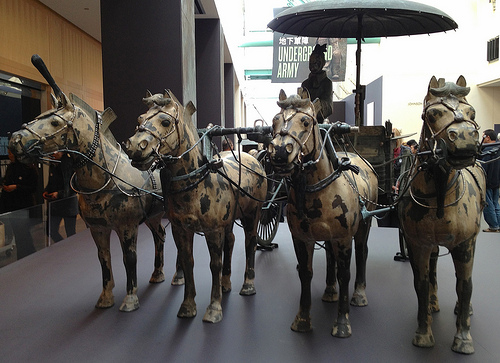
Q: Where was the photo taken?
A: It was taken at the museum.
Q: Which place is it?
A: It is a museum.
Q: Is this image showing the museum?
A: Yes, it is showing the museum.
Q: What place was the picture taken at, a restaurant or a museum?
A: It was taken at a museum.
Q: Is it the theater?
A: No, it is the museum.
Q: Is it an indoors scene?
A: Yes, it is indoors.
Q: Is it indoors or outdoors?
A: It is indoors.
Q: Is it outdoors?
A: No, it is indoors.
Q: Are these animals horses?
A: Yes, all the animals are horses.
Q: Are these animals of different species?
A: No, all the animals are horses.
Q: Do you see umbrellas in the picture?
A: Yes, there is an umbrella.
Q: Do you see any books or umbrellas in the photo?
A: Yes, there is an umbrella.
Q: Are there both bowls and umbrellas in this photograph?
A: No, there is an umbrella but no bowls.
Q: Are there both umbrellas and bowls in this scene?
A: No, there is an umbrella but no bowls.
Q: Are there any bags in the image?
A: No, there are no bags.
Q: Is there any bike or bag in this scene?
A: No, there are no bags or bikes.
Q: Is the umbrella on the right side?
A: Yes, the umbrella is on the right of the image.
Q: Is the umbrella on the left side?
A: No, the umbrella is on the right of the image.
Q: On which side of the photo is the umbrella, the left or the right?
A: The umbrella is on the right of the image.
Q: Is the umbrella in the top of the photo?
A: Yes, the umbrella is in the top of the image.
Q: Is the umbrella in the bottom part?
A: No, the umbrella is in the top of the image.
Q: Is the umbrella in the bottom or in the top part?
A: The umbrella is in the top of the image.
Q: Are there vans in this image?
A: No, there are no vans.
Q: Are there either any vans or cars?
A: No, there are no vans or cars.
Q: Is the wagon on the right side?
A: Yes, the wagon is on the right of the image.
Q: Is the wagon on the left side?
A: No, the wagon is on the right of the image.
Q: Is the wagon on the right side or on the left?
A: The wagon is on the right of the image.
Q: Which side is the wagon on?
A: The wagon is on the right of the image.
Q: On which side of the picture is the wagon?
A: The wagon is on the right of the image.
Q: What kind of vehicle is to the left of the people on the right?
A: The vehicle is a wagon.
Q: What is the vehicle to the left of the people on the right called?
A: The vehicle is a wagon.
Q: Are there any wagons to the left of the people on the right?
A: Yes, there is a wagon to the left of the people.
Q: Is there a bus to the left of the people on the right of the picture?
A: No, there is a wagon to the left of the people.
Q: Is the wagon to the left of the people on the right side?
A: Yes, the wagon is to the left of the people.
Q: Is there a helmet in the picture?
A: No, there are no helmets.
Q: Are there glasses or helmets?
A: No, there are no helmets or glasses.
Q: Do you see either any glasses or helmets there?
A: No, there are no helmets or glasses.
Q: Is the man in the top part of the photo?
A: Yes, the man is in the top of the image.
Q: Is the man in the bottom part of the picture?
A: No, the man is in the top of the image.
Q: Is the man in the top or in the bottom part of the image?
A: The man is in the top of the image.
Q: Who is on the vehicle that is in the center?
A: The man is on the carriage.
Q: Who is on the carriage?
A: The man is on the carriage.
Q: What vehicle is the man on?
A: The man is on the carriage.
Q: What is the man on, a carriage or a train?
A: The man is on a carriage.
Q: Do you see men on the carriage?
A: Yes, there is a man on the carriage.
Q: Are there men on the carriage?
A: Yes, there is a man on the carriage.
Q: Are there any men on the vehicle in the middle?
A: Yes, there is a man on the carriage.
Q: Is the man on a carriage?
A: Yes, the man is on a carriage.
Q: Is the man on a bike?
A: No, the man is on a carriage.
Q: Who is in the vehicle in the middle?
A: The man is in the carriage.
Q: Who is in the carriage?
A: The man is in the carriage.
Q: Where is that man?
A: The man is in the carriage.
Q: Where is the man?
A: The man is in the carriage.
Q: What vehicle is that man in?
A: The man is in the carriage.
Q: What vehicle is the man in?
A: The man is in the carriage.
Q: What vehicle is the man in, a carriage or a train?
A: The man is in a carriage.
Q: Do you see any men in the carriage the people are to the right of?
A: Yes, there is a man in the carriage.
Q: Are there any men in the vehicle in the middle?
A: Yes, there is a man in the carriage.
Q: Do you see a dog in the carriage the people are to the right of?
A: No, there is a man in the carriage.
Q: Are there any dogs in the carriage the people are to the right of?
A: No, there is a man in the carriage.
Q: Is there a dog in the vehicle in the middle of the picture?
A: No, there is a man in the carriage.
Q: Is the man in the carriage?
A: Yes, the man is in the carriage.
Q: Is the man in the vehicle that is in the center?
A: Yes, the man is in the carriage.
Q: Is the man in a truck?
A: No, the man is in the carriage.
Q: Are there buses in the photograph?
A: No, there are no buses.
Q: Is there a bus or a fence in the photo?
A: No, there are no buses or fences.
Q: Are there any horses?
A: Yes, there are horses.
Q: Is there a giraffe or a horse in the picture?
A: Yes, there are horses.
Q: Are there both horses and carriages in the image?
A: Yes, there are both horses and a carriage.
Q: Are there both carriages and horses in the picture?
A: Yes, there are both horses and a carriage.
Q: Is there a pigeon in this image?
A: No, there are no pigeons.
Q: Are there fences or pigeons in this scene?
A: No, there are no pigeons or fences.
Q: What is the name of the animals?
A: The animals are horses.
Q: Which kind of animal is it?
A: The animals are horses.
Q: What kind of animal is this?
A: These are horses.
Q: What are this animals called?
A: These are horses.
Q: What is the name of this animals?
A: These are horses.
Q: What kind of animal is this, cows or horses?
A: These are horses.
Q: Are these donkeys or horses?
A: These are horses.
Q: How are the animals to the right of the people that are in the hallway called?
A: The animals are horses.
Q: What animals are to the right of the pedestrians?
A: The animals are horses.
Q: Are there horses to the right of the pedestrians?
A: Yes, there are horses to the right of the pedestrians.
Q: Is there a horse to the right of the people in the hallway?
A: Yes, there are horses to the right of the pedestrians.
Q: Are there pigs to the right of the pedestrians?
A: No, there are horses to the right of the pedestrians.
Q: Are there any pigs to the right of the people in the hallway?
A: No, there are horses to the right of the pedestrians.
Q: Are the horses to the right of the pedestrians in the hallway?
A: Yes, the horses are to the right of the pedestrians.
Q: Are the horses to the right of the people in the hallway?
A: Yes, the horses are to the right of the pedestrians.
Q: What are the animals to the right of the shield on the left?
A: The animals are horses.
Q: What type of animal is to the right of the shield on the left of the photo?
A: The animals are horses.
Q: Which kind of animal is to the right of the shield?
A: The animals are horses.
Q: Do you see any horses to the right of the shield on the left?
A: Yes, there are horses to the right of the shield.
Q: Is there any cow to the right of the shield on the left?
A: No, there are horses to the right of the shield.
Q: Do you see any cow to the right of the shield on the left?
A: No, there are horses to the right of the shield.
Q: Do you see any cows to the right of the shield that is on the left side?
A: No, there are horses to the right of the shield.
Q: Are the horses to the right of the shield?
A: Yes, the horses are to the right of the shield.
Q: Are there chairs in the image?
A: No, there are no chairs.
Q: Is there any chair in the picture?
A: No, there are no chairs.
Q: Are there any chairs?
A: No, there are no chairs.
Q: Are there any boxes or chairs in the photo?
A: No, there are no chairs or boxes.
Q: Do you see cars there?
A: No, there are no cars.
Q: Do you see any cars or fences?
A: No, there are no cars or fences.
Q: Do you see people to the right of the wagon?
A: Yes, there are people to the right of the wagon.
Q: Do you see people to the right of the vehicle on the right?
A: Yes, there are people to the right of the wagon.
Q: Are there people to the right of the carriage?
A: Yes, there are people to the right of the carriage.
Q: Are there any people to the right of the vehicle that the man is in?
A: Yes, there are people to the right of the carriage.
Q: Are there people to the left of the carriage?
A: No, the people are to the right of the carriage.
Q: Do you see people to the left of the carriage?
A: No, the people are to the right of the carriage.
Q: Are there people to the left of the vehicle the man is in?
A: No, the people are to the right of the carriage.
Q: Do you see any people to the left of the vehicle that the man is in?
A: No, the people are to the right of the carriage.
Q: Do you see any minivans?
A: No, there are no minivans.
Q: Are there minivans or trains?
A: No, there are no minivans or trains.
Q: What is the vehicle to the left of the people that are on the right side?
A: The vehicle is a carriage.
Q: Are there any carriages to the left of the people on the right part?
A: Yes, there is a carriage to the left of the people.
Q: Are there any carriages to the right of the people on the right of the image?
A: No, the carriage is to the left of the people.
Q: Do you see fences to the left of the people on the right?
A: No, there is a carriage to the left of the people.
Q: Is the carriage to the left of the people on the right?
A: Yes, the carriage is to the left of the people.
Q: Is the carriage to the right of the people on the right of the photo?
A: No, the carriage is to the left of the people.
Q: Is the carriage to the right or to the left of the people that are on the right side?
A: The carriage is to the left of the people.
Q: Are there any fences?
A: No, there are no fences.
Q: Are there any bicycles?
A: No, there are no bicycles.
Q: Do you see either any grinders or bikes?
A: No, there are no bikes or grinders.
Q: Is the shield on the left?
A: Yes, the shield is on the left of the image.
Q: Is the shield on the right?
A: No, the shield is on the left of the image.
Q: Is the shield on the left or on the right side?
A: The shield is on the left of the image.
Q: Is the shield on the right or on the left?
A: The shield is on the left of the image.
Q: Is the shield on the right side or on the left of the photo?
A: The shield is on the left of the image.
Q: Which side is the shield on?
A: The shield is on the left of the image.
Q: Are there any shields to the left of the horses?
A: Yes, there is a shield to the left of the horses.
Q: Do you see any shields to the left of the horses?
A: Yes, there is a shield to the left of the horses.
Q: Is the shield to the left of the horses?
A: Yes, the shield is to the left of the horses.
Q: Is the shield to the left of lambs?
A: No, the shield is to the left of the horses.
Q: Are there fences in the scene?
A: No, there are no fences.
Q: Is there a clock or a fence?
A: No, there are no fences or clocks.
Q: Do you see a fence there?
A: No, there are no fences.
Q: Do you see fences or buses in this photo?
A: No, there are no fences or buses.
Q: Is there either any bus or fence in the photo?
A: No, there are no fences or buses.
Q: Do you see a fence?
A: No, there are no fences.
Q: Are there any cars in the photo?
A: No, there are no cars.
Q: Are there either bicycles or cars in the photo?
A: No, there are no cars or bicycles.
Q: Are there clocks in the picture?
A: No, there are no clocks.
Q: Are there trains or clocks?
A: No, there are no clocks or trains.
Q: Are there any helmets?
A: No, there are no helmets.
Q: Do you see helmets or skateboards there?
A: No, there are no helmets or skateboards.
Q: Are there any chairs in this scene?
A: No, there are no chairs.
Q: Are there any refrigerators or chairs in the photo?
A: No, there are no chairs or refrigerators.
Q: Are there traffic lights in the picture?
A: No, there are no traffic lights.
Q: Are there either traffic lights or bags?
A: No, there are no traffic lights or bags.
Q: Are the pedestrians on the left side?
A: Yes, the pedestrians are on the left of the image.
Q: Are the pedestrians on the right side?
A: No, the pedestrians are on the left of the image.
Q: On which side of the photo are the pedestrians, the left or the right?
A: The pedestrians are on the left of the image.